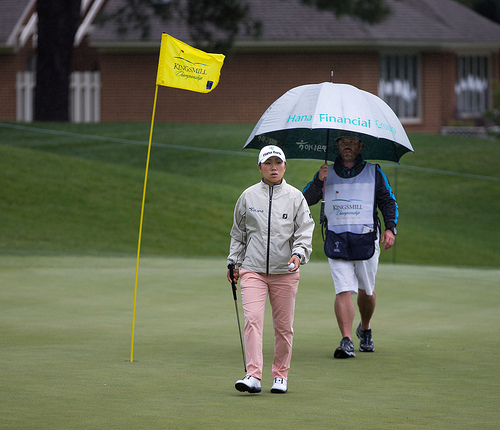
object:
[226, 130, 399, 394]
people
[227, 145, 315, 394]
woman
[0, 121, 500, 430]
course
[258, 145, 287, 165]
hat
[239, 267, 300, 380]
pants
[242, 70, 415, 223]
umbrella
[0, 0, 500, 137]
building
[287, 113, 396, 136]
word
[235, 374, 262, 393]
shoe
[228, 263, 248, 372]
club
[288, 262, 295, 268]
ball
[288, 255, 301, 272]
hand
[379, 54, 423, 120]
window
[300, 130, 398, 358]
man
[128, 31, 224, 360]
flag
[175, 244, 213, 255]
grass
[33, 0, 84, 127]
tree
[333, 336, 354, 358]
shoe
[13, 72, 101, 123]
fence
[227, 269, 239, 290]
hand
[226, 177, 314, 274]
jacket